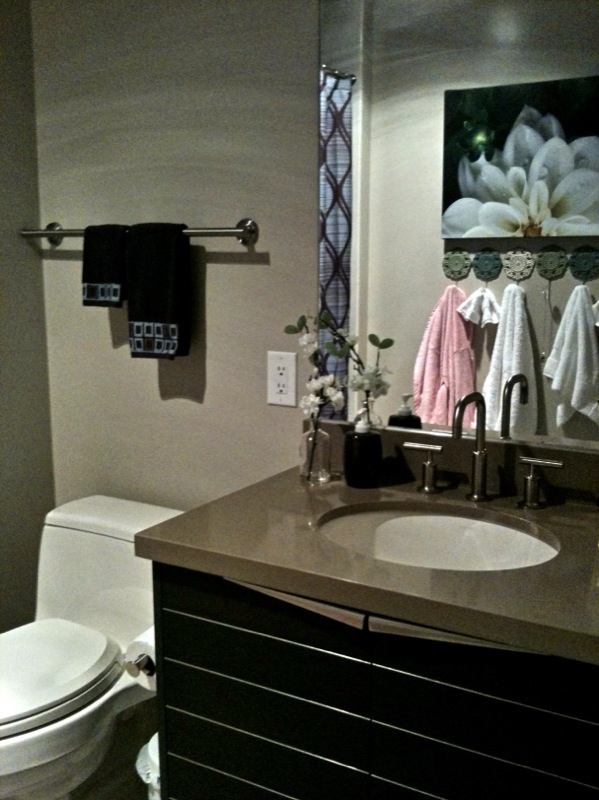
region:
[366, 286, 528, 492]
a view of tap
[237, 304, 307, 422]
a view of swtich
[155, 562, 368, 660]
black panel is long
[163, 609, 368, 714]
black panel is long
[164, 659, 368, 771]
black panel is long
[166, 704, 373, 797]
black panel is long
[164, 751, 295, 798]
black panel is long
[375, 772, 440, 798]
black panel is long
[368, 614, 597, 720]
black panel is long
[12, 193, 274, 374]
towel rack with two towels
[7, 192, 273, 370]
Towel rack mounted next to vanity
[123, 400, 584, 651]
Single bowl vanity top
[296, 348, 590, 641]
Vanity bowl and facuets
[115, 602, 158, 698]
roll of toilet paper on side of vanity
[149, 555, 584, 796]
Doors of dark colored vanity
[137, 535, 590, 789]
Doors of dark colored single bowl vanity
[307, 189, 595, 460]
Mirror mounted over vanity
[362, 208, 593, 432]
Reflection in mirror over vanity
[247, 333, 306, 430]
Wall mounted electrical outlet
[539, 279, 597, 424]
a white dry hanging towel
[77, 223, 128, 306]
a black dry hanging towel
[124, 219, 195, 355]
a black dry hanging towel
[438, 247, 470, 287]
a decorative towel hook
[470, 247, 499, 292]
a decorative towel hook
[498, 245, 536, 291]
a decorative towel hook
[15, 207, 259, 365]
Towel rack with brown towels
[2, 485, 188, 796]
White toilet with lid down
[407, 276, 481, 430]
Pink towel above bathroom sink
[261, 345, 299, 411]
Electric outlet on wall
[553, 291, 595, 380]
a white towel hanging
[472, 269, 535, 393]
a white towel hanging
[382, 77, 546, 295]
a picture on the wall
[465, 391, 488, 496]
a bathroom sink faucet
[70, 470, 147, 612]
a bathroom toilet is white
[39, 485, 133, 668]
a toilet is white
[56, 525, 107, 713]
a bathroom toilet is white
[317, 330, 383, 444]
a flower in the vase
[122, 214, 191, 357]
cotton on towel in the bathroom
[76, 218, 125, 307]
cotton on towel in the bathroom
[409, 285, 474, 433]
cotton on towel in the bathroom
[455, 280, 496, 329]
cotton on towel in the bathroom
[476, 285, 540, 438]
cotton on towel in the bathroom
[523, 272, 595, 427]
cotton on towel in the bathroom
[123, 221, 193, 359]
cotton on towel in the bathroom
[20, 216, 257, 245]
Stainless steel towel bar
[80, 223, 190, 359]
Two black and white hand towels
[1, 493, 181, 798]
White modern toilet with plastic lid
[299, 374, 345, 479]
White flowers in a clear glass jar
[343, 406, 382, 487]
Black soap bottle with a white pump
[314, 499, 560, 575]
Ocal under-counter mounted bathroom sink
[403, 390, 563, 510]
Modern style bathroom faucet and taps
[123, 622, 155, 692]
Roll of white toilet tissue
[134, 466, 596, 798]
Bathroom vanity with black drawers and gray countertop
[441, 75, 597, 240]
Decorative picture of a white flower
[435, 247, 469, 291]
A hook on the wall.